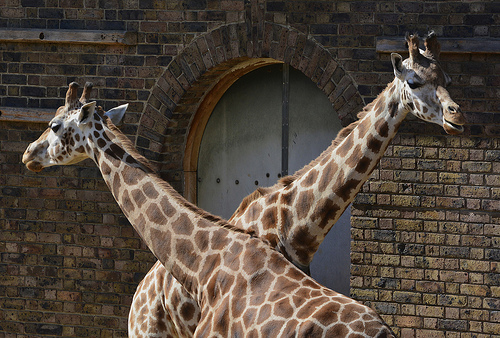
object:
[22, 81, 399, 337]
giraffe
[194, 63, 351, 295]
door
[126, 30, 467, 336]
giraffe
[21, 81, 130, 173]
head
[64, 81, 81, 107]
horns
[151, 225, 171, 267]
spot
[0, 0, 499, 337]
building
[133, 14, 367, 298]
archway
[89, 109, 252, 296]
neck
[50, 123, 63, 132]
eye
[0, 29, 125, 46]
line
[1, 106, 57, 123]
line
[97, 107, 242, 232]
mane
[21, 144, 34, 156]
nose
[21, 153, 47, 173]
mouth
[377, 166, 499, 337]
wall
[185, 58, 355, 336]
window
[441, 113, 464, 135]
mouth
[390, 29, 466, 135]
head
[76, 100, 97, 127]
ear